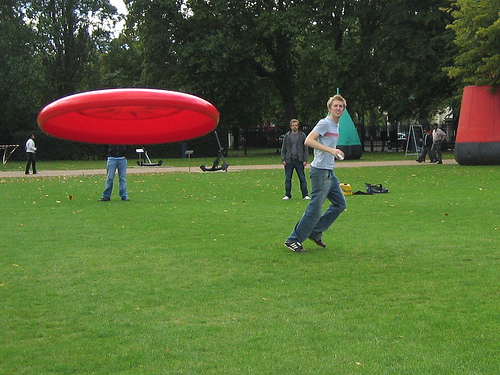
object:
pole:
[451, 84, 499, 166]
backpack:
[352, 182, 389, 195]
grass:
[0, 257, 498, 371]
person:
[23, 131, 40, 173]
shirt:
[23, 139, 38, 153]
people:
[431, 120, 448, 165]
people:
[101, 142, 129, 201]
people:
[415, 125, 429, 164]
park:
[1, 6, 500, 375]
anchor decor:
[199, 148, 230, 172]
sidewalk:
[0, 155, 457, 182]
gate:
[358, 123, 404, 152]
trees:
[119, 0, 288, 164]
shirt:
[309, 115, 339, 171]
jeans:
[287, 164, 344, 244]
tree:
[0, 0, 121, 156]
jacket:
[281, 130, 308, 162]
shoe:
[280, 237, 306, 252]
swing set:
[403, 124, 426, 159]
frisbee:
[34, 87, 220, 146]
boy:
[285, 94, 349, 252]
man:
[275, 115, 312, 202]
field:
[0, 147, 500, 375]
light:
[89, 1, 132, 41]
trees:
[345, 0, 500, 156]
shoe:
[307, 233, 325, 249]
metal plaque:
[185, 150, 194, 155]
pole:
[188, 153, 191, 172]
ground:
[15, 170, 482, 254]